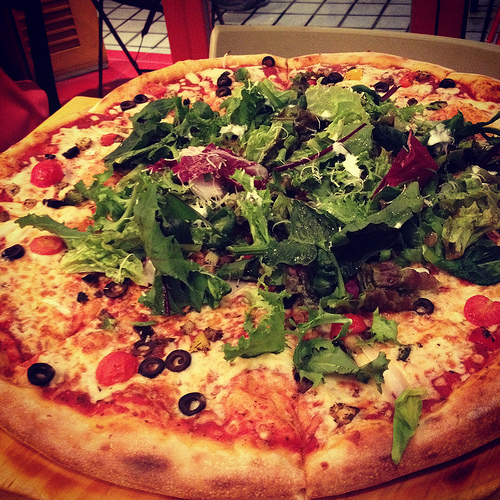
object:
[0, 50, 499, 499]
pizza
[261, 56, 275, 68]
olive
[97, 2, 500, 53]
floor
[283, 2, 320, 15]
tile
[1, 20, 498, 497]
board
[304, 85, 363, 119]
leaf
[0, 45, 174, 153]
rug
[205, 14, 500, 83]
chair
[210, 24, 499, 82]
top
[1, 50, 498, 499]
crust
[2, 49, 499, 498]
cheese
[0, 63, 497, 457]
sauce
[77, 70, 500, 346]
salad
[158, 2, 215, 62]
column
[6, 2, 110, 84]
door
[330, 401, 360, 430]
mushroom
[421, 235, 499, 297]
spinach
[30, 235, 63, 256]
pepperoni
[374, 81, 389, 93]
olive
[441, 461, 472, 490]
knot